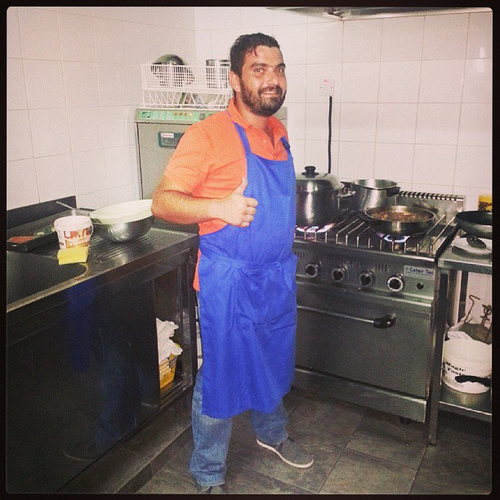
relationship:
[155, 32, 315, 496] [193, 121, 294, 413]
man wears apron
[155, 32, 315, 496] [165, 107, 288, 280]
man in shirt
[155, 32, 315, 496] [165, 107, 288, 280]
man wears shirt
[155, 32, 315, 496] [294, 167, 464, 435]
man uses stove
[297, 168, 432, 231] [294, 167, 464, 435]
food on stove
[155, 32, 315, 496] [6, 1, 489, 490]
man in kitchen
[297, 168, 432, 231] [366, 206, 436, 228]
food in frying pan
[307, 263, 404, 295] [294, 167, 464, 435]
knobs on stove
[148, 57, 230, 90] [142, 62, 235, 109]
bowls in rack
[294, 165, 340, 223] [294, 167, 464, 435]
pot on stove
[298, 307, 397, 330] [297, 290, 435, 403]
handle on oven door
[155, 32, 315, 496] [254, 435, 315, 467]
man wears sneakers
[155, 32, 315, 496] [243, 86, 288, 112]
man wears beard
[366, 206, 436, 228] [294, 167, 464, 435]
frying pan on stove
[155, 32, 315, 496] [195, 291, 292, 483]
man wears jeans